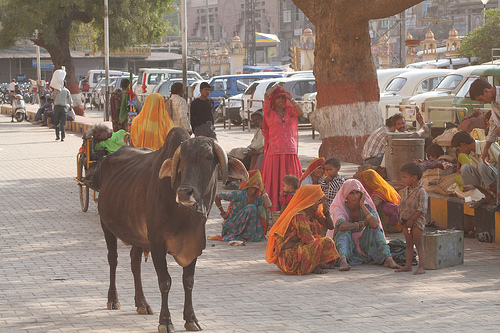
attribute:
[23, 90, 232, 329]
cow — brown, standing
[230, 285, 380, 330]
sidewalk — red, stone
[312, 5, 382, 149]
trunk — large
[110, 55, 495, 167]
cars — parked, aligned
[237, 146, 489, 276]
children — sitting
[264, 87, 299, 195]
woman — standing, red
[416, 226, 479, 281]
suitcase — small, grey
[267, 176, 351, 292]
outfit — orange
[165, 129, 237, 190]
horns — downward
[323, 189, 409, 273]
woman — pink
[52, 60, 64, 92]
bag — white, large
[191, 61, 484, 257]
people — sitting, gathered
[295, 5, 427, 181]
tree — large, painted, brown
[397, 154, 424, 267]
boy — barefoot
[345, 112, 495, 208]
men — sitting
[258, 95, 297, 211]
outfit — red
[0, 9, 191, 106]
tree — green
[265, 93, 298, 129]
shawl — pink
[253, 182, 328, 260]
shawl — orange